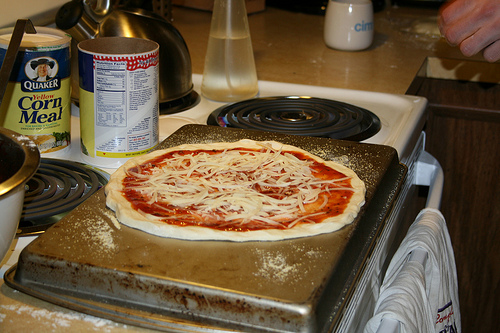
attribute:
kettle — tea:
[51, 1, 209, 117]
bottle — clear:
[206, 17, 259, 97]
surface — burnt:
[226, 106, 451, 230]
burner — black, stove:
[205, 92, 376, 149]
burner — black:
[16, 144, 108, 224]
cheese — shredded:
[122, 141, 354, 229]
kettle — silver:
[57, 1, 190, 96]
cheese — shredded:
[201, 165, 261, 200]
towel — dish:
[370, 203, 461, 330]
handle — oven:
[403, 132, 449, 209]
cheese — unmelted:
[131, 147, 343, 219]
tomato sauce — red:
[205, 185, 277, 230]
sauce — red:
[141, 193, 170, 212]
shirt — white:
[364, 208, 461, 331]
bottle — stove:
[199, 1, 261, 101]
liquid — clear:
[206, 37, 254, 98]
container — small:
[76, 35, 161, 168]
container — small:
[1, 26, 70, 153]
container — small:
[56, 26, 216, 237]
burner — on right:
[224, 85, 372, 146]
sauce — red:
[119, 146, 353, 236]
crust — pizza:
[128, 223, 337, 244]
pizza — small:
[106, 140, 364, 243]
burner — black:
[14, 155, 101, 234]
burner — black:
[211, 90, 381, 140]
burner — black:
[15, 156, 104, 228]